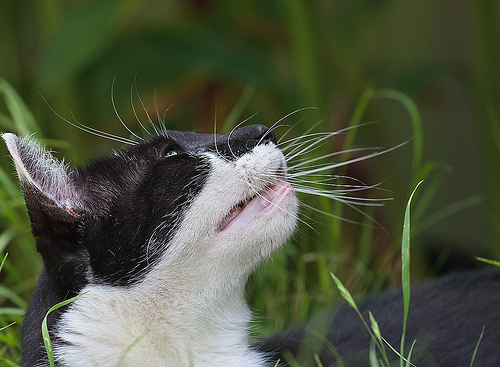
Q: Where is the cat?
A: In the garden.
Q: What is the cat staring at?
A: A bird on a tree.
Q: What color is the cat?
A: Black and white.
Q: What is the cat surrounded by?
A: Long grass.